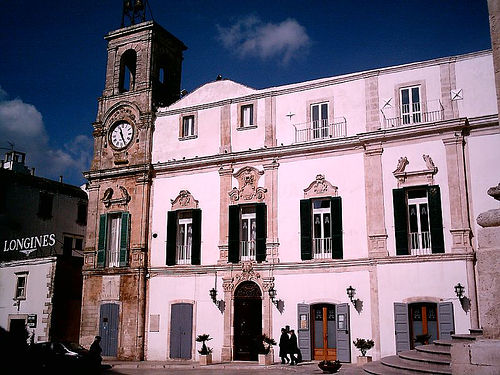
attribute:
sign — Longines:
[2, 227, 67, 266]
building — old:
[43, 15, 497, 370]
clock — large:
[108, 119, 138, 154]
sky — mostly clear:
[185, 2, 490, 49]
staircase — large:
[364, 331, 478, 371]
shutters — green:
[93, 209, 108, 280]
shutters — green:
[118, 207, 135, 269]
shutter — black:
[425, 184, 445, 254]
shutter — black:
[389, 186, 409, 256]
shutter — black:
[326, 195, 344, 260]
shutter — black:
[297, 199, 315, 261]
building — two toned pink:
[131, 48, 495, 374]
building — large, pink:
[78, 20, 498, 364]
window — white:
[97, 209, 132, 269]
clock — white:
[107, 122, 138, 150]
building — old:
[78, 16, 186, 356]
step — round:
[366, 350, 444, 372]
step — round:
[376, 356, 451, 373]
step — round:
[397, 346, 451, 366]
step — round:
[416, 347, 453, 356]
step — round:
[434, 337, 452, 347]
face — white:
[109, 122, 131, 146]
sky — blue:
[2, 1, 498, 188]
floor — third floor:
[151, 43, 498, 173]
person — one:
[277, 326, 291, 364]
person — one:
[287, 326, 302, 364]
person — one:
[276, 324, 286, 373]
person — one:
[288, 328, 298, 368]